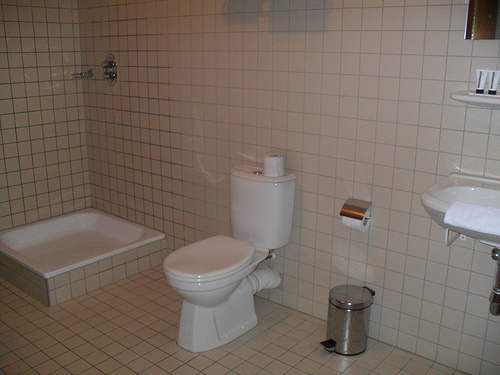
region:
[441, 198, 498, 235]
White towel hanging on sink.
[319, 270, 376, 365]
Metal round trash can on floor.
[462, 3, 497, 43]
Bathroom mirror hanging on wall.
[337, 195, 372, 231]
Roll of toilet roll in wall holder.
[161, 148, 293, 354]
White toilet in bathroom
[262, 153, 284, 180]
Roll of toilet paper on toilet.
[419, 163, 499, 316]
White bathroom sink bowl.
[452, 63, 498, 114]
White shelf with two bottles on it.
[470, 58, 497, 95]
Two small bottles with black caps.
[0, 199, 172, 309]
White shower base with beige tiles.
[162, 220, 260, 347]
this is a toilet sink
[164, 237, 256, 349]
the sink is closed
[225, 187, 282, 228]
this is the container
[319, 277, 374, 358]
this is a container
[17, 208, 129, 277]
this is the sink floor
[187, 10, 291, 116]
this is the wall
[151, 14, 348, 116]
the wall is tiled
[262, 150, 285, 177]
this is a tissue paper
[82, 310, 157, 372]
this is the floor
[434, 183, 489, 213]
this is a sink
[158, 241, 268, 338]
this is a toilet bowl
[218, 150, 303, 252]
this is a cister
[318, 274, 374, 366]
this is a dustbin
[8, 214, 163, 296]
this is a bath tub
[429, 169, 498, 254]
this is a sink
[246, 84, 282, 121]
these are wall tiles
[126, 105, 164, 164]
these are wall tiles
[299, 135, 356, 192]
these are wall tiles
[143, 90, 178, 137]
these are wall tiles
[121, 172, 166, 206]
these are wall tiles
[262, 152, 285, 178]
fresh roll of toilet paper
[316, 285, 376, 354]
Metal trash can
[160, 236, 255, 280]
Lid on a toilet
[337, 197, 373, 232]
Toilet paper dispenser with a roll on it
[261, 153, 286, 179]
new roll of toielt paper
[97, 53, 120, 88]
A shower mechanism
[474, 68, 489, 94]
Black and white tube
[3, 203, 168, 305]
A shower stall without doors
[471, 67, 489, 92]
White tube by a sink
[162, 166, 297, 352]
A bathroom toilet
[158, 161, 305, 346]
a clean white toilet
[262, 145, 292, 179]
some white toilet paper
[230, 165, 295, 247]
the tank of a toilet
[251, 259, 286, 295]
the pipe of a toilet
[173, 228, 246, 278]
the lid of a toilet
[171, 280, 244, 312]
the bowl of a toilet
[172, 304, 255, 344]
the base of a toilet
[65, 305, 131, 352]
the floor tile of a bathroom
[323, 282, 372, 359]
a metal bathroom trashcan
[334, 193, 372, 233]
a roll of toilet paper